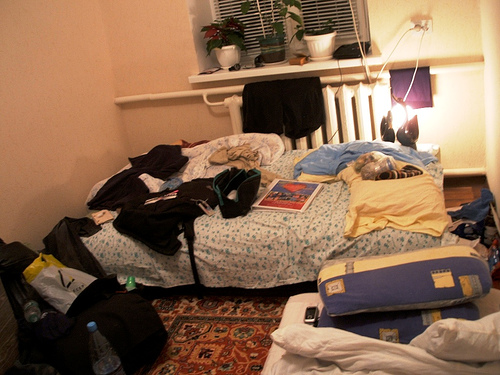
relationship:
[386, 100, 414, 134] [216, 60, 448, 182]
light hanging down from headboard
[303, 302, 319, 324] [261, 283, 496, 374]
cell phone on chair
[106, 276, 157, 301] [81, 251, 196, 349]
bottle in bag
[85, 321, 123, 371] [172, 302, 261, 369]
bottle on floor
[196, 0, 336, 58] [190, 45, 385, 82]
plants on window sill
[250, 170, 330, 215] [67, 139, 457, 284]
book on bed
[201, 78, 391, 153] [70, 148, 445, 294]
radiator by bed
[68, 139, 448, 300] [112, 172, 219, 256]
bed with thing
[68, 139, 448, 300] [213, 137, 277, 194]
bed with thing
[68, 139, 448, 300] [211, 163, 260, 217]
bed with thing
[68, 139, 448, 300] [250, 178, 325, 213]
bed with magazine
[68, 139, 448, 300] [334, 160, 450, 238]
bed with pillow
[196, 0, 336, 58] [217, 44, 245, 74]
plants in a pot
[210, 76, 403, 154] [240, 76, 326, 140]
radiator has black shorts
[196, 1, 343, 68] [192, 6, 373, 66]
plants on window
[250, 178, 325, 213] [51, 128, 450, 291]
magazine on bed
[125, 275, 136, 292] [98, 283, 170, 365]
bottle in bag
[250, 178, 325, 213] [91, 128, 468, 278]
magazine next to bed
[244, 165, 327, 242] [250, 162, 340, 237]
magazine with cover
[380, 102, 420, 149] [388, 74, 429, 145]
lamp with no shade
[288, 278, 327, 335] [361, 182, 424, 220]
cell phone next to pillow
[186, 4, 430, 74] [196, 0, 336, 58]
window behind plants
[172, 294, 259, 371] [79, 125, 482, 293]
rug below bed